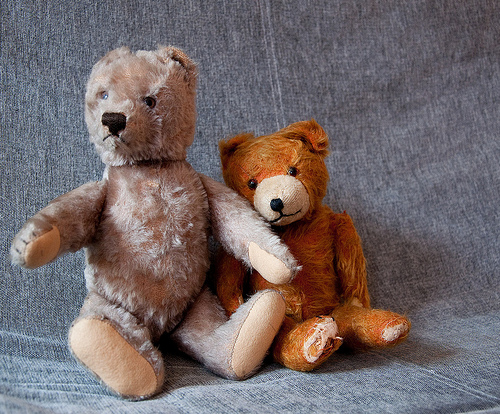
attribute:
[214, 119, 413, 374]
teddy bear —  teddy,  muzzle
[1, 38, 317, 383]
bear — teddy  , nose , mouth 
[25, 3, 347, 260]
bears — two stuffed 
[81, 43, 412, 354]
bears — Two teddy 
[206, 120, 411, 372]
bear — worn out , teddy 